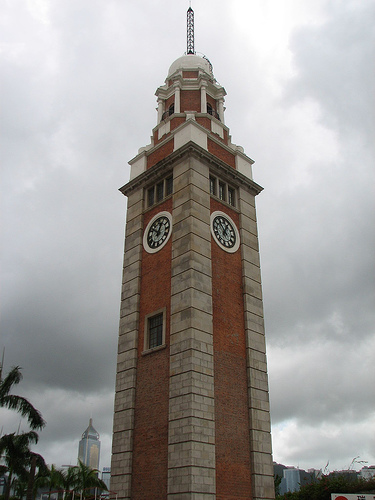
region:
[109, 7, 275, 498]
A large clock tower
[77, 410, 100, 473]
A large tower in the distance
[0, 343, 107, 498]
A small group of palm trees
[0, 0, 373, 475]
A grey cloudy sky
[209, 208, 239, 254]
A clock on a tower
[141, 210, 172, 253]
A clock on a tower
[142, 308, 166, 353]
A window on a tower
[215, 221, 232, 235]
The hands of a clock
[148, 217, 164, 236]
The hands of a clock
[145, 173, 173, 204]
some windows on a tower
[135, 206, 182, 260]
black and white clock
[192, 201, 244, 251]
black and white clock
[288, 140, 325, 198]
white clouds in blue sky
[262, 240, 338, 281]
white clouds in blue sky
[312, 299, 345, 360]
white clouds in blue sky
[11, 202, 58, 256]
white clouds in blue sky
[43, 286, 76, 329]
white clouds in blue sky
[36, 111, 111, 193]
white clouds in blue sky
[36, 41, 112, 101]
white clouds in blue sky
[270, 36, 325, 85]
white clouds in blue sky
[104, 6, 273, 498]
THIS IS A TALL BUILDING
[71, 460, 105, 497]
this is a tree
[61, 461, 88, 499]
this is a tree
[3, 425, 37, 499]
this is a tree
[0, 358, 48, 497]
this is a tree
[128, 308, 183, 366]
a window in the building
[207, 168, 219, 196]
a window in the building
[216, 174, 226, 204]
a window in the building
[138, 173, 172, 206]
a window in the building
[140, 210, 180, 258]
this is a clock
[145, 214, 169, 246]
black and white clock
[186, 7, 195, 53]
lightning rod on tower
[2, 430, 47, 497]
tree with green palms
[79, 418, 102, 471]
blue and tan tower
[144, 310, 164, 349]
slone window on tower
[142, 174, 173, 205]
stone windows in tower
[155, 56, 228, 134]
brick and stone clock tower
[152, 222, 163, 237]
black hands on clock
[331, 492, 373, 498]
white bill board by trees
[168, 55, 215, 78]
white stone dome on tower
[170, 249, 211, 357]
A stone wall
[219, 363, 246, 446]
A brick wall in the photo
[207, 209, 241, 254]
A clock in the photo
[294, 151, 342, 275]
Cloudy skies in the photo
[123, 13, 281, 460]
A tower in the photo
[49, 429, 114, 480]
Buildings in the background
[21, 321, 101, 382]
Heavy clouds in the photo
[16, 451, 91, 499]
Trees in the photo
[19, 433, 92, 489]
Tree branches in the photo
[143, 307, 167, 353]
A window on the building